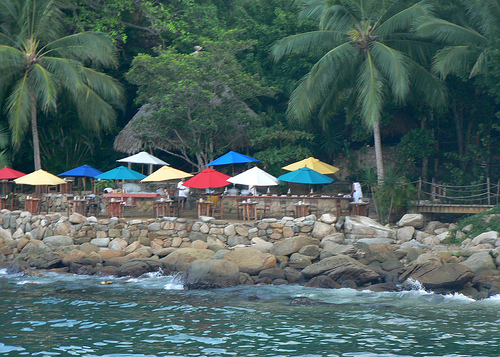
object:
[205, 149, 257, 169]
umbrellas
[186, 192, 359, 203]
table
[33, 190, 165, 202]
tables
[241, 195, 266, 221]
chairs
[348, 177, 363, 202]
person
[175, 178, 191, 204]
person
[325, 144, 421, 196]
hut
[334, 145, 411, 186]
wall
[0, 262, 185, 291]
waves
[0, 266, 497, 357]
ocean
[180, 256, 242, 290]
rocks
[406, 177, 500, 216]
bridge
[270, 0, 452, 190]
palms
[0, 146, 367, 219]
restaurant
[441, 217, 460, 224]
stream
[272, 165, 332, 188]
umbrella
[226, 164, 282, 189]
umbrella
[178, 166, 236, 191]
umbrella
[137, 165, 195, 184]
umbrella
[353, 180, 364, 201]
uniform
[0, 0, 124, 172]
palm tree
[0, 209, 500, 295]
wall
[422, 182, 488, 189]
ropes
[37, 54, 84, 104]
leaves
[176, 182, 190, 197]
shirt